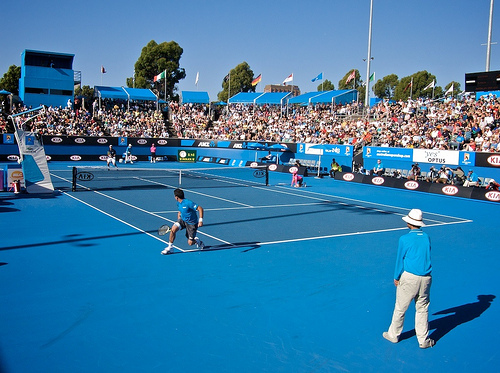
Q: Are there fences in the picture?
A: No, there are no fences.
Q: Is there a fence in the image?
A: No, there are no fences.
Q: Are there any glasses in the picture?
A: No, there are no glasses.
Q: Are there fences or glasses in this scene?
A: No, there are no glasses or fences.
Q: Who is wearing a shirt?
A: The man is wearing a shirt.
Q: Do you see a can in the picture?
A: No, there are no cans.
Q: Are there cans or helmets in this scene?
A: No, there are no cans or helmets.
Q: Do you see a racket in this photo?
A: Yes, there is a racket.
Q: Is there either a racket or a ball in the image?
A: Yes, there is a racket.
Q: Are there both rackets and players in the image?
A: Yes, there are both a racket and a player.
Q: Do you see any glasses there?
A: No, there are no glasses.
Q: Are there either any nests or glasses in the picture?
A: No, there are no glasses or nests.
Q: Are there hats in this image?
A: Yes, there is a hat.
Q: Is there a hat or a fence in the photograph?
A: Yes, there is a hat.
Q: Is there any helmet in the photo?
A: No, there are no helmets.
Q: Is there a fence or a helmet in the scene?
A: No, there are no helmets or fences.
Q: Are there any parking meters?
A: No, there are no parking meters.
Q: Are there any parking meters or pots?
A: No, there are no parking meters or pots.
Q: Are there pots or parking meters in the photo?
A: No, there are no parking meters or pots.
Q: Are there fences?
A: No, there are no fences.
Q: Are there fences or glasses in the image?
A: No, there are no fences or glasses.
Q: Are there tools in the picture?
A: No, there are no tools.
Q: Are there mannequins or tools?
A: No, there are no tools or mannequins.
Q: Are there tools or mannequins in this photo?
A: No, there are no tools or mannequins.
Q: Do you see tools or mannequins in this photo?
A: No, there are no tools or mannequins.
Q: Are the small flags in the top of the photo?
A: Yes, the flags are in the top of the image.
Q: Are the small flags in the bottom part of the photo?
A: No, the flags are in the top of the image.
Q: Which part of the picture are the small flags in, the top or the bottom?
A: The flags are in the top of the image.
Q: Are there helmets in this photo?
A: No, there are no helmets.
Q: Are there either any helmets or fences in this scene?
A: No, there are no helmets or fences.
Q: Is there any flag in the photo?
A: Yes, there is a flag.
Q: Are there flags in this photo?
A: Yes, there is a flag.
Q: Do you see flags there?
A: Yes, there is a flag.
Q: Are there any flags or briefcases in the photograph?
A: Yes, there is a flag.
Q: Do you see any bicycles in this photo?
A: No, there are no bicycles.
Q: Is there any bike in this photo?
A: No, there are no bikes.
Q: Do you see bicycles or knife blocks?
A: No, there are no bicycles or knife blocks.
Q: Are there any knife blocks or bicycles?
A: No, there are no bicycles or knife blocks.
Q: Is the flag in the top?
A: Yes, the flag is in the top of the image.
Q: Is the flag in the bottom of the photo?
A: No, the flag is in the top of the image.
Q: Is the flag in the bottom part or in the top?
A: The flag is in the top of the image.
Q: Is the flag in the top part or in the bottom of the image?
A: The flag is in the top of the image.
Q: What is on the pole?
A: The flag is on the pole.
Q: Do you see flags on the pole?
A: Yes, there is a flag on the pole.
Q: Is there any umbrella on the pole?
A: No, there is a flag on the pole.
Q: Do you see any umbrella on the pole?
A: No, there is a flag on the pole.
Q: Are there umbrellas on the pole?
A: No, there is a flag on the pole.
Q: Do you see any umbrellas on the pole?
A: No, there is a flag on the pole.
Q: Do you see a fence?
A: No, there are no fences.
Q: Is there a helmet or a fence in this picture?
A: No, there are no fences or helmets.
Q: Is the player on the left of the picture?
A: Yes, the player is on the left of the image.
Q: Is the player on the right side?
A: No, the player is on the left of the image.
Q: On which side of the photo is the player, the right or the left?
A: The player is on the left of the image.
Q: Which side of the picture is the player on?
A: The player is on the left of the image.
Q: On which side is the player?
A: The player is on the left of the image.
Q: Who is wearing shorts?
A: The player is wearing shorts.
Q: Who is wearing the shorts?
A: The player is wearing shorts.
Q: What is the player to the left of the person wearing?
A: The player is wearing shorts.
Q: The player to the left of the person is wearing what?
A: The player is wearing shorts.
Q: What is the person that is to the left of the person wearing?
A: The player is wearing shorts.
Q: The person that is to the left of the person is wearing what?
A: The player is wearing shorts.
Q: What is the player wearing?
A: The player is wearing shorts.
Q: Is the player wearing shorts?
A: Yes, the player is wearing shorts.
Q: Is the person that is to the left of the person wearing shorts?
A: Yes, the player is wearing shorts.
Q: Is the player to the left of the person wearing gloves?
A: No, the player is wearing shorts.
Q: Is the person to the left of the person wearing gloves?
A: No, the player is wearing shorts.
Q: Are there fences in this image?
A: No, there are no fences.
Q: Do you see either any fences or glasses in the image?
A: No, there are no fences or glasses.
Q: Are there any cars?
A: No, there are no cars.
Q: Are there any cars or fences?
A: No, there are no cars or fences.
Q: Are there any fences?
A: No, there are no fences.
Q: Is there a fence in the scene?
A: No, there are no fences.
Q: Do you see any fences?
A: No, there are no fences.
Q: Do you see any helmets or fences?
A: No, there are no fences or helmets.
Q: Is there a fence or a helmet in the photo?
A: No, there are no fences or helmets.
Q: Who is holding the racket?
A: The man is holding the racket.